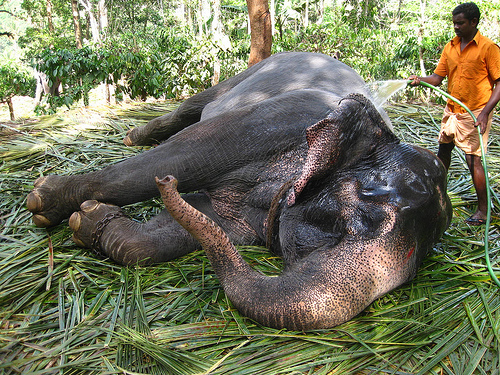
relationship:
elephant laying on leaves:
[27, 50, 457, 327] [0, 91, 500, 371]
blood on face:
[402, 243, 417, 260] [150, 174, 437, 334]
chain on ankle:
[86, 207, 133, 252] [96, 210, 122, 255]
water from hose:
[345, 73, 420, 114] [404, 71, 499, 288]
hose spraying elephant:
[404, 71, 499, 288] [27, 50, 457, 327]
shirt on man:
[405, 29, 483, 111] [422, 6, 494, 215]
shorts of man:
[438, 111, 482, 158] [435, 3, 499, 75]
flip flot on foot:
[454, 188, 486, 242] [465, 202, 487, 249]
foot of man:
[465, 202, 487, 249] [415, 1, 498, 227]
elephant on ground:
[27, 50, 457, 327] [0, 102, 500, 374]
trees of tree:
[0, 0, 499, 114] [179, 10, 329, 53]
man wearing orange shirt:
[406, 3, 499, 226] [431, 30, 498, 113]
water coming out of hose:
[355, 80, 407, 114] [404, 71, 499, 288]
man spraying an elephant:
[418, 1, 488, 227] [27, 50, 457, 327]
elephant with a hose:
[27, 50, 457, 327] [385, 67, 495, 291]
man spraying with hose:
[418, 1, 488, 227] [385, 67, 495, 291]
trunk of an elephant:
[153, 172, 420, 333] [27, 50, 457, 327]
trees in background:
[42, 5, 218, 98] [17, 10, 434, 113]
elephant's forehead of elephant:
[154, 94, 453, 331] [27, 50, 457, 327]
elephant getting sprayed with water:
[27, 50, 457, 327] [366, 70, 411, 120]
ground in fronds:
[32, 201, 404, 372] [0, 100, 500, 370]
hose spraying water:
[404, 71, 499, 288] [344, 72, 411, 115]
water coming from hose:
[355, 80, 407, 114] [383, 63, 453, 136]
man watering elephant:
[406, 3, 499, 226] [80, 12, 463, 332]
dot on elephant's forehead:
[399, 245, 417, 265] [145, 110, 459, 342]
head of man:
[443, 0, 486, 52] [435, 1, 498, 98]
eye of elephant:
[362, 211, 377, 236] [141, 90, 413, 330]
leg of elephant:
[25, 95, 226, 269] [27, 50, 457, 327]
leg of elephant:
[18, 112, 290, 226] [27, 50, 457, 327]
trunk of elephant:
[153, 172, 420, 333] [27, 50, 457, 327]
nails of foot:
[25, 176, 52, 224] [26, 172, 76, 229]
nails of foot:
[68, 197, 96, 245] [68, 197, 121, 249]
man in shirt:
[406, 3, 499, 226] [431, 30, 483, 112]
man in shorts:
[406, 3, 499, 226] [429, 105, 483, 158]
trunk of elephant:
[153, 176, 367, 332] [27, 50, 457, 327]